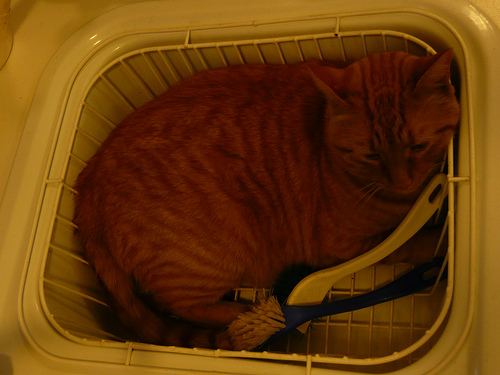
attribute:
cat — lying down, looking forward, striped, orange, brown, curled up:
[67, 43, 464, 351]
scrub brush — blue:
[217, 254, 452, 352]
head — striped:
[305, 46, 461, 195]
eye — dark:
[353, 147, 382, 166]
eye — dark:
[403, 138, 429, 155]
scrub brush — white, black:
[266, 171, 440, 331]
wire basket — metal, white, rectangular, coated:
[34, 28, 458, 364]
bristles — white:
[226, 297, 288, 348]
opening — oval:
[424, 183, 443, 205]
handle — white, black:
[371, 169, 451, 267]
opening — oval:
[416, 264, 440, 279]